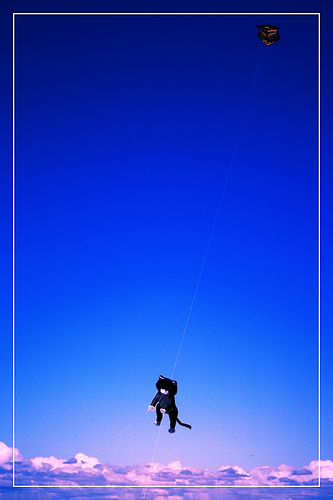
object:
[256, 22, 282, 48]
kite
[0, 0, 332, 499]
sky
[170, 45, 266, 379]
string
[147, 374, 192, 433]
cat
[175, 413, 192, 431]
tail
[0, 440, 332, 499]
cloud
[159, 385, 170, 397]
snout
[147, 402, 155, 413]
paws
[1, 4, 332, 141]
top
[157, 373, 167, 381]
ears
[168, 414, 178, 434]
legs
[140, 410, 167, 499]
strings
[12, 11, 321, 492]
border